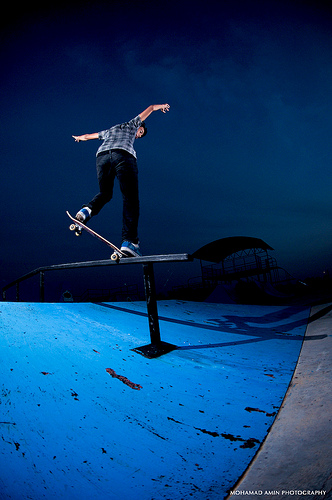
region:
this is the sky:
[214, 30, 299, 109]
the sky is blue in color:
[208, 128, 293, 164]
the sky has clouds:
[72, 12, 296, 61]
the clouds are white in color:
[87, 16, 198, 51]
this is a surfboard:
[63, 209, 129, 261]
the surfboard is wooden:
[92, 234, 101, 240]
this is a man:
[76, 103, 183, 254]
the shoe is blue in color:
[121, 243, 127, 246]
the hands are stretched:
[63, 104, 172, 146]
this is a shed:
[175, 227, 282, 292]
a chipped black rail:
[6, 250, 197, 354]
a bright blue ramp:
[14, 291, 307, 483]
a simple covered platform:
[185, 231, 314, 298]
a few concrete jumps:
[204, 277, 298, 311]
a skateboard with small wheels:
[60, 209, 129, 267]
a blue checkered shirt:
[96, 116, 144, 159]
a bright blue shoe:
[115, 237, 145, 260]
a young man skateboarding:
[65, 98, 172, 260]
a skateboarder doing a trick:
[69, 98, 172, 264]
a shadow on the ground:
[140, 288, 326, 352]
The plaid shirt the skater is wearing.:
[98, 125, 139, 157]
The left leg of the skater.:
[95, 154, 112, 214]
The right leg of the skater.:
[114, 170, 138, 242]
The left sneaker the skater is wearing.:
[73, 206, 87, 218]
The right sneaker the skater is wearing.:
[121, 242, 143, 256]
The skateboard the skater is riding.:
[66, 211, 132, 257]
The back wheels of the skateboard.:
[67, 223, 80, 234]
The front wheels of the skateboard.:
[110, 248, 117, 262]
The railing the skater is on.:
[41, 253, 192, 269]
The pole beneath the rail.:
[139, 262, 170, 356]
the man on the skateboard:
[65, 102, 169, 260]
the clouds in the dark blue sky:
[0, 0, 330, 303]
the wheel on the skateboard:
[110, 252, 118, 260]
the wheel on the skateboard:
[69, 223, 75, 230]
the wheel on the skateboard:
[75, 229, 81, 236]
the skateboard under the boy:
[64, 208, 127, 261]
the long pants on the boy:
[82, 150, 139, 244]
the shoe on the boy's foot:
[74, 209, 88, 222]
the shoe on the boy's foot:
[120, 240, 142, 257]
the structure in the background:
[190, 234, 282, 302]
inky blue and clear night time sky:
[10, 7, 330, 295]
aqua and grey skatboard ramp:
[2, 284, 327, 490]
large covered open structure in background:
[188, 231, 279, 293]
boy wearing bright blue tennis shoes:
[77, 203, 144, 254]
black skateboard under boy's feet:
[63, 205, 125, 253]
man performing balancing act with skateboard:
[49, 94, 188, 272]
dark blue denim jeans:
[85, 152, 139, 242]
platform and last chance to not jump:
[52, 247, 187, 266]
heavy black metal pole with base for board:
[130, 261, 172, 361]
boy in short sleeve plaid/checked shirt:
[96, 113, 142, 157]